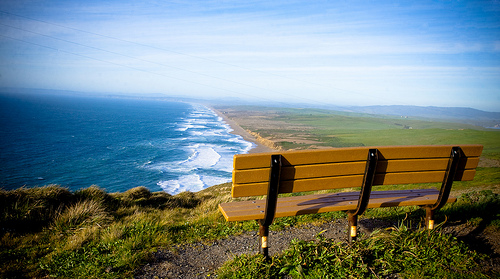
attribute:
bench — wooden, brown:
[218, 146, 483, 259]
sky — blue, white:
[1, 1, 499, 113]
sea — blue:
[1, 87, 252, 196]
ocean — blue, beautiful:
[0, 91, 251, 197]